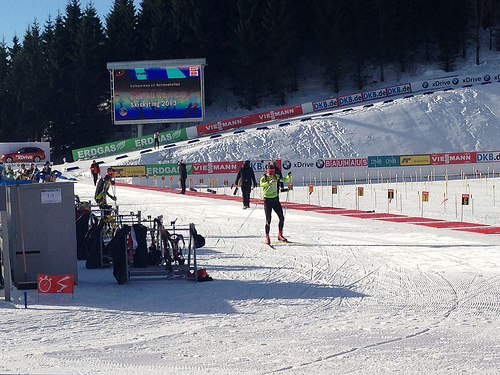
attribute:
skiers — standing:
[205, 157, 299, 235]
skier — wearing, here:
[231, 164, 298, 231]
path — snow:
[258, 258, 430, 375]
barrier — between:
[308, 153, 415, 223]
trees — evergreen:
[182, 29, 323, 94]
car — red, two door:
[17, 149, 54, 176]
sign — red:
[49, 270, 87, 300]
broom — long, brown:
[8, 184, 55, 269]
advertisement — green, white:
[123, 138, 203, 142]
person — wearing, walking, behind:
[244, 157, 293, 209]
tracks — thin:
[241, 224, 465, 344]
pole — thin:
[285, 182, 309, 232]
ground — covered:
[207, 280, 318, 356]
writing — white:
[204, 117, 243, 134]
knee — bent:
[268, 213, 305, 245]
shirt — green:
[261, 177, 283, 194]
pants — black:
[229, 178, 264, 217]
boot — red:
[181, 259, 217, 288]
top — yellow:
[252, 179, 303, 206]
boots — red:
[261, 220, 309, 252]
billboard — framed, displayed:
[90, 44, 227, 133]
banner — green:
[62, 139, 116, 161]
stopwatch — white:
[34, 275, 63, 303]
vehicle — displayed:
[10, 145, 81, 164]